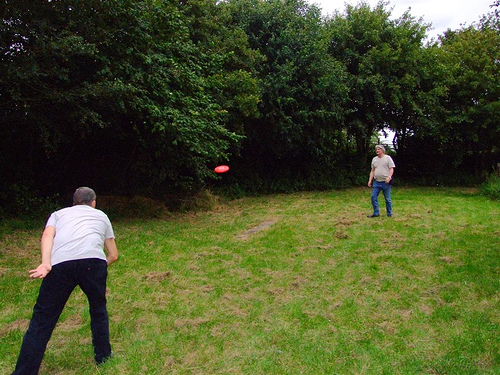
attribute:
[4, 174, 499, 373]
yard — part , brown grassy, green 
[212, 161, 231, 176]
disc — red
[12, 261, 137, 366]
jeans — black 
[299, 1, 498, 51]
sky — white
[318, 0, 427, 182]
tree — large green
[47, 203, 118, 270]
shirt — man's white 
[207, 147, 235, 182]
frisbee air — red 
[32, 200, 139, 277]
shirt — white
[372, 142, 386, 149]
hair — white  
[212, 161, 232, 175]
frisbee — red  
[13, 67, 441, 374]
men — two older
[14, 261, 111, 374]
pants —  man's blue jean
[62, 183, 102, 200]
hair — man's short cut gray 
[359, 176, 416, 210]
jeans — blue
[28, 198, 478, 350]
patches — brown 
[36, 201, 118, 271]
shirt — white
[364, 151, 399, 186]
shirt — tan 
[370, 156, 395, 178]
shirt — man's, gray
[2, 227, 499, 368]
grass — green 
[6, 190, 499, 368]
yard — green